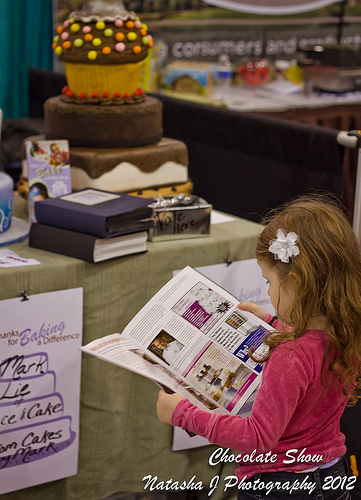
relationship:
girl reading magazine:
[155, 191, 359, 495] [72, 261, 285, 440]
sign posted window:
[171, 33, 356, 58] [129, 1, 356, 73]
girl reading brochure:
[155, 191, 359, 500] [92, 256, 280, 448]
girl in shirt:
[155, 191, 359, 495] [168, 313, 356, 486]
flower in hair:
[263, 228, 302, 263] [267, 191, 360, 401]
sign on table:
[1, 286, 81, 493] [0, 190, 272, 498]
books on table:
[26, 187, 156, 264] [0, 190, 272, 498]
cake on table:
[17, 0, 190, 208] [0, 190, 272, 498]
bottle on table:
[217, 53, 230, 92] [141, 27, 357, 235]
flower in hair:
[268, 228, 300, 263] [257, 201, 357, 393]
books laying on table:
[38, 196, 142, 263] [7, 132, 282, 489]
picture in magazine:
[121, 294, 273, 409] [84, 269, 293, 435]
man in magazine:
[123, 323, 212, 376] [84, 269, 293, 435]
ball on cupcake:
[87, 51, 103, 61] [47, 9, 151, 97]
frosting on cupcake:
[50, 5, 153, 60] [46, 5, 156, 104]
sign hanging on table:
[1, 286, 81, 493] [5, 174, 269, 490]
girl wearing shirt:
[155, 191, 359, 500] [171, 326, 350, 467]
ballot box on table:
[101, 180, 245, 262] [1, 134, 311, 497]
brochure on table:
[20, 132, 81, 232] [0, 169, 286, 499]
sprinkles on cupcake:
[87, 50, 96, 58] [52, 10, 155, 105]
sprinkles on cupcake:
[132, 46, 140, 53] [52, 10, 155, 105]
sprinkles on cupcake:
[102, 47, 110, 53] [52, 10, 155, 105]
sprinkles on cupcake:
[62, 42, 69, 48] [52, 10, 155, 105]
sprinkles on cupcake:
[96, 22, 104, 28] [52, 10, 155, 105]